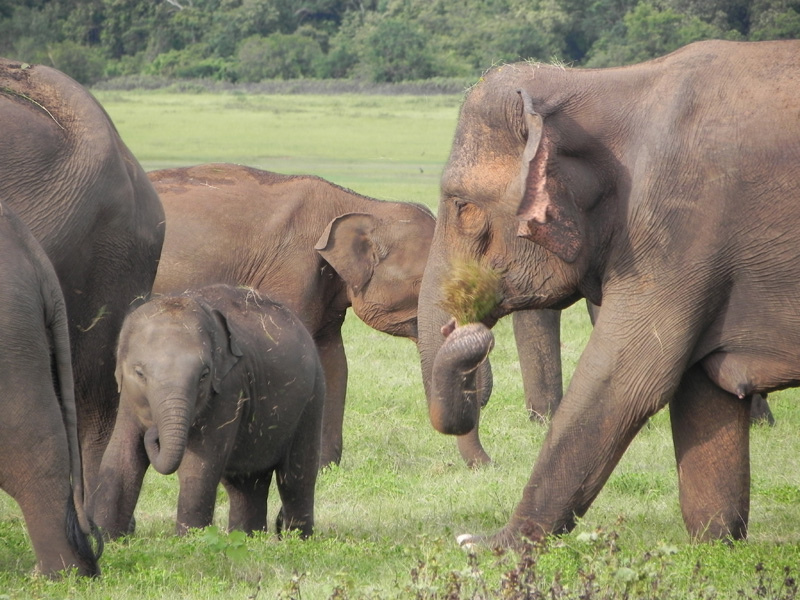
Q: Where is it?
A: This is at the field.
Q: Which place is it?
A: It is a field.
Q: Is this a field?
A: Yes, it is a field.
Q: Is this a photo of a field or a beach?
A: It is showing a field.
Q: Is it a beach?
A: No, it is a field.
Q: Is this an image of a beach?
A: No, the picture is showing a field.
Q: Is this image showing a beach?
A: No, the picture is showing a field.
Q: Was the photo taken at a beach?
A: No, the picture was taken in a field.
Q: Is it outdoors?
A: Yes, it is outdoors.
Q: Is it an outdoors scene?
A: Yes, it is outdoors.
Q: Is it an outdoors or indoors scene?
A: It is outdoors.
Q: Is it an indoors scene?
A: No, it is outdoors.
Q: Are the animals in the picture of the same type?
A: Yes, all the animals are elephants.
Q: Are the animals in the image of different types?
A: No, all the animals are elephants.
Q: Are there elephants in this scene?
A: Yes, there is an elephant.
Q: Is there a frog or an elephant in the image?
A: Yes, there is an elephant.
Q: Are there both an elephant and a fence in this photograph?
A: No, there is an elephant but no fences.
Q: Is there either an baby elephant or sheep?
A: Yes, there is a baby elephant.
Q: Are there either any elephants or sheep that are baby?
A: Yes, the elephant is a baby.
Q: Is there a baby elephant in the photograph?
A: Yes, there is a baby elephant.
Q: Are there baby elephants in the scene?
A: Yes, there is a baby elephant.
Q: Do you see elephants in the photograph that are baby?
A: Yes, there is an elephant that is a baby.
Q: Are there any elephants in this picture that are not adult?
A: Yes, there is an baby elephant.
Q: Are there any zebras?
A: No, there are no zebras.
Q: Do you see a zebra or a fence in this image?
A: No, there are no zebras or fences.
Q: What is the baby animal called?
A: The animal is an elephant.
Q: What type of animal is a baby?
A: The animal is an elephant.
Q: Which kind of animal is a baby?
A: The animal is an elephant.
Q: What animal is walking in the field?
A: The animal is an elephant.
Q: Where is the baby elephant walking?
A: The elephant is walking in the field.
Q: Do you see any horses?
A: No, there are no horses.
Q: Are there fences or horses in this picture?
A: No, there are no horses or fences.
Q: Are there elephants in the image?
A: Yes, there is an elephant.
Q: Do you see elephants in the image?
A: Yes, there is an elephant.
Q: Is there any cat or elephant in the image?
A: Yes, there is an elephant.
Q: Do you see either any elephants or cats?
A: Yes, there is an elephant.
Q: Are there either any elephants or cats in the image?
A: Yes, there is an elephant.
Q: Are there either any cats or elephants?
A: Yes, there is an elephant.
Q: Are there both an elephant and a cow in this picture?
A: No, there is an elephant but no cows.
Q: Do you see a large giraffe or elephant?
A: Yes, there is a large elephant.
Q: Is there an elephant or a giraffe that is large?
A: Yes, the elephant is large.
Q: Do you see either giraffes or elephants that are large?
A: Yes, the elephant is large.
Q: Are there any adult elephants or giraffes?
A: Yes, there is an adult elephant.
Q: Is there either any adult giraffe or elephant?
A: Yes, there is an adult elephant.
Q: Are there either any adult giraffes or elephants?
A: Yes, there is an adult elephant.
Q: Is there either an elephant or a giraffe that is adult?
A: Yes, the elephant is adult.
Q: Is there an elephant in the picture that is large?
A: Yes, there is a large elephant.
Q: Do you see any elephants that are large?
A: Yes, there is an elephant that is large.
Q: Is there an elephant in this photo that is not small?
A: Yes, there is a large elephant.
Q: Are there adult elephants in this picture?
A: Yes, there is an adult elephant.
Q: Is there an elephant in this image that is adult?
A: Yes, there is an elephant that is adult.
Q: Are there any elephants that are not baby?
A: Yes, there is a adult elephant.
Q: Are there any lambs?
A: No, there are no lambs.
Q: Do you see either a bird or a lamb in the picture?
A: No, there are no lambs or birds.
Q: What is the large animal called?
A: The animal is an elephant.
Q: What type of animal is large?
A: The animal is an elephant.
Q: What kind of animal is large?
A: The animal is an elephant.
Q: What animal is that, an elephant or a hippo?
A: That is an elephant.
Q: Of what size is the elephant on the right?
A: The elephant is large.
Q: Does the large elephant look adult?
A: Yes, the elephant is adult.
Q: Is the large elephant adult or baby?
A: The elephant is adult.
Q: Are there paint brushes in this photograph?
A: No, there are no paint brushes.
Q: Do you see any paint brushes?
A: No, there are no paint brushes.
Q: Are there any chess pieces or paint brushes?
A: No, there are no paint brushes or chess pieces.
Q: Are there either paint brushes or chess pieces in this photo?
A: No, there are no paint brushes or chess pieces.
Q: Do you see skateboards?
A: No, there are no skateboards.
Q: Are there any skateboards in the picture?
A: No, there are no skateboards.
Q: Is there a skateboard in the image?
A: No, there are no skateboards.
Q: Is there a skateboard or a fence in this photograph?
A: No, there are no skateboards or fences.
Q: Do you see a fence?
A: No, there are no fences.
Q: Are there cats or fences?
A: No, there are no fences or cats.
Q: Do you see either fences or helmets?
A: No, there are no fences or helmets.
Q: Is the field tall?
A: Yes, the field is tall.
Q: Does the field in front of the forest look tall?
A: Yes, the field is tall.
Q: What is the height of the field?
A: The field is tall.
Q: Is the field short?
A: No, the field is tall.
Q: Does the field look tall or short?
A: The field is tall.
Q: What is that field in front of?
A: The field is in front of the forest.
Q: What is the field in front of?
A: The field is in front of the forest.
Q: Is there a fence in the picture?
A: No, there are no fences.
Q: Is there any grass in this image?
A: Yes, there is grass.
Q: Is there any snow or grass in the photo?
A: Yes, there is grass.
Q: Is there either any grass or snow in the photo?
A: Yes, there is grass.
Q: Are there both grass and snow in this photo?
A: No, there is grass but no snow.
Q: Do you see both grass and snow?
A: No, there is grass but no snow.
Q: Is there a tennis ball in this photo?
A: No, there are no tennis balls.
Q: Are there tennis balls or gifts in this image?
A: No, there are no tennis balls or gifts.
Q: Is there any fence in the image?
A: No, there are no fences.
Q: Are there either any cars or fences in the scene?
A: No, there are no fences or cars.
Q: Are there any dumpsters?
A: No, there are no dumpsters.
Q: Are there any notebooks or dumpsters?
A: No, there are no dumpsters or notebooks.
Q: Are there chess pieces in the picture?
A: No, there are no chess pieces.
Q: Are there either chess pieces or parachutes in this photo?
A: No, there are no chess pieces or parachutes.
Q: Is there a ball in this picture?
A: No, there are no balls.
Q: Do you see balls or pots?
A: No, there are no balls or pots.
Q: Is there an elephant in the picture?
A: Yes, there is an elephant.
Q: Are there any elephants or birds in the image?
A: Yes, there is an elephant.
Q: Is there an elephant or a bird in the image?
A: Yes, there is an elephant.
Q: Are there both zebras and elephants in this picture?
A: No, there is an elephant but no zebras.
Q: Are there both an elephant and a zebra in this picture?
A: No, there is an elephant but no zebras.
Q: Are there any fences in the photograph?
A: No, there are no fences.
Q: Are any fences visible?
A: No, there are no fences.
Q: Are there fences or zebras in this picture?
A: No, there are no fences or zebras.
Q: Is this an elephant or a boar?
A: This is an elephant.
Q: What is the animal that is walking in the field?
A: The animal is an elephant.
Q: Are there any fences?
A: No, there are no fences.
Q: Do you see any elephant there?
A: Yes, there is an elephant.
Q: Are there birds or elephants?
A: Yes, there is an elephant.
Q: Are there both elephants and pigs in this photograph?
A: No, there is an elephant but no pigs.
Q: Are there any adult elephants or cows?
A: Yes, there is an adult elephant.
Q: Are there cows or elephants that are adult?
A: Yes, the elephant is adult.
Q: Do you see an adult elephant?
A: Yes, there is an adult elephant.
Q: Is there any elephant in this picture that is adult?
A: Yes, there is an elephant that is adult.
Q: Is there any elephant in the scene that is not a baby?
A: Yes, there is a adult elephant.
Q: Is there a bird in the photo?
A: No, there are no birds.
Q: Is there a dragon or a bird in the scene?
A: No, there are no birds or dragons.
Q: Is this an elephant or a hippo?
A: This is an elephant.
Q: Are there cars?
A: No, there are no cars.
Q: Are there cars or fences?
A: No, there are no cars or fences.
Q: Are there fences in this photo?
A: No, there are no fences.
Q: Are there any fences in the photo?
A: No, there are no fences.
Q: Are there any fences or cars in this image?
A: No, there are no fences or cars.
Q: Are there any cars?
A: No, there are no cars.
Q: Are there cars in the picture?
A: No, there are no cars.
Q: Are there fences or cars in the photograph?
A: No, there are no cars or fences.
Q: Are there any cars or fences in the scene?
A: No, there are no cars or fences.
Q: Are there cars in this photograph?
A: No, there are no cars.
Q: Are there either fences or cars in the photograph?
A: No, there are no cars or fences.